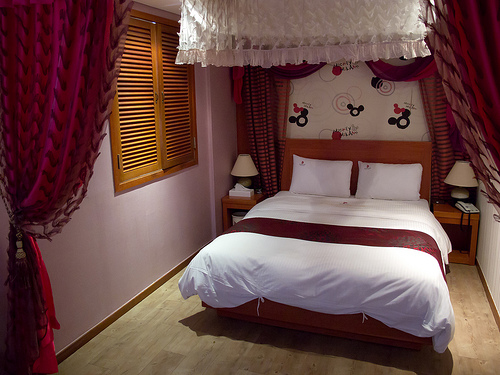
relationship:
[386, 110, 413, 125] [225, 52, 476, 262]
ears painted on wall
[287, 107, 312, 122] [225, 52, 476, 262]
ears painted on wall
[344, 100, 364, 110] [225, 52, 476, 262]
ears painted on wall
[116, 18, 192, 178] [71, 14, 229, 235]
blinds on a window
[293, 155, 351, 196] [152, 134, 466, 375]
pillow on bed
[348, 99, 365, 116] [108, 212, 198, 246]
decal on wall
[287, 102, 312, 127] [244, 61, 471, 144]
decal on wall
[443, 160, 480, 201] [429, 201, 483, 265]
lamp on nightstand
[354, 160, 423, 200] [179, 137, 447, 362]
pillow on bed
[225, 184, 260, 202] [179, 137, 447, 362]
tissues next to bed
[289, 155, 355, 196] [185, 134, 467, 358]
pillow on a bed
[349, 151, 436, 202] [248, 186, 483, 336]
pillow on a bed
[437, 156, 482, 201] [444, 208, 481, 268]
lamp on a endstone